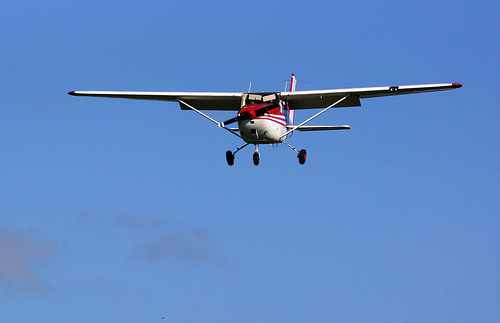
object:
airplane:
[53, 56, 476, 172]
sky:
[3, 3, 499, 63]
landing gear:
[214, 137, 314, 174]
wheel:
[218, 147, 236, 172]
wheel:
[249, 149, 262, 168]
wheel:
[290, 146, 313, 166]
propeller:
[208, 96, 293, 136]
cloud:
[0, 203, 243, 322]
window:
[240, 90, 262, 104]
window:
[261, 90, 279, 103]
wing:
[275, 80, 463, 112]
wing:
[64, 85, 246, 113]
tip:
[446, 75, 467, 100]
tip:
[55, 87, 77, 103]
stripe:
[250, 104, 299, 132]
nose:
[226, 96, 292, 151]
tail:
[285, 69, 298, 130]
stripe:
[212, 119, 229, 131]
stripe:
[281, 65, 299, 143]